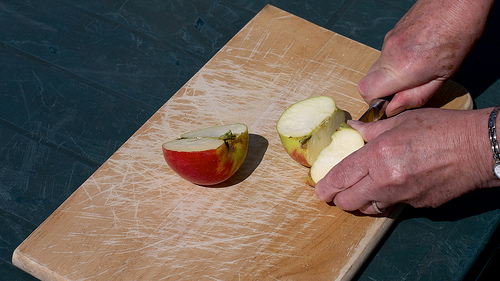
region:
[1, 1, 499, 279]
The table is blue.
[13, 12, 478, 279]
The cutting board has many scratches.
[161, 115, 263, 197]
The apple is halved.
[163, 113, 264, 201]
The apple has a stem.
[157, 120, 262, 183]
The apple is ripe.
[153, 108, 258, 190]
The apple is uneaten.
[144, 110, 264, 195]
The apple is unpeeled.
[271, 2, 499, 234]
Apple is being cut.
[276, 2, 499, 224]
Ring on the left hand.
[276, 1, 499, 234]
Watch on left wrist.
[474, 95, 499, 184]
a watch on a left wrist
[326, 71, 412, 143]
a knife for cutting an apple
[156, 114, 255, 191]
one half of an apple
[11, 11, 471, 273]
a cutting board with cuts in it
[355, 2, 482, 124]
right hand of cutter of fruit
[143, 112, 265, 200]
a red and green apple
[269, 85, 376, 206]
a half of an apple being halved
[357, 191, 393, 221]
wedding ring on a man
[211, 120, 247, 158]
the stem of an apple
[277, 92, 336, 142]
the cut surface of a slice of apple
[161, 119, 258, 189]
Half of an apple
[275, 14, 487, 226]
Hands slicing an apple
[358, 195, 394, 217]
Ring on a finger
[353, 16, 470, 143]
Hand holding knife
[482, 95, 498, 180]
Bracelet on wrist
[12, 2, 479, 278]
Wooden cutting board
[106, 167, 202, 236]
Scratches on the cutting board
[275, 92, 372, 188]
Half of an apple being sliced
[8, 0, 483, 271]
Cutting board with apple on a table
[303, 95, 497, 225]
Left hand holding piece of apple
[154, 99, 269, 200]
a half part of an apple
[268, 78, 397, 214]
an apple being sliced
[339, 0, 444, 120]
a hand holding a knife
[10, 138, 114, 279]
a wooden chopping board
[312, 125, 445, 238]
a hand holding an apple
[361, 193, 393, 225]
a ring in the finger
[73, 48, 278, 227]
an apple on a chopping board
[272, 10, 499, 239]
a person slicing an apple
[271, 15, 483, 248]
a person slicing an apple on a chopping board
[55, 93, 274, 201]
a half piece of a ripe apple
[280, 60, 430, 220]
a person is cutting an apple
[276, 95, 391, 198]
the apple is being cut into quarters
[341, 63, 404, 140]
a person is cutting an apple by knife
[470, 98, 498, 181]
a lady is wearing a watch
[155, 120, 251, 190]
an apple half is on the cutting board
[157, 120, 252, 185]
the apple is green and red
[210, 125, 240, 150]
a stem is in the apple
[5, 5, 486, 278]
the cutting board is on a table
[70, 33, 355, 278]
the cutting board has many scratchjes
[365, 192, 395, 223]
the lady has a wedding band on